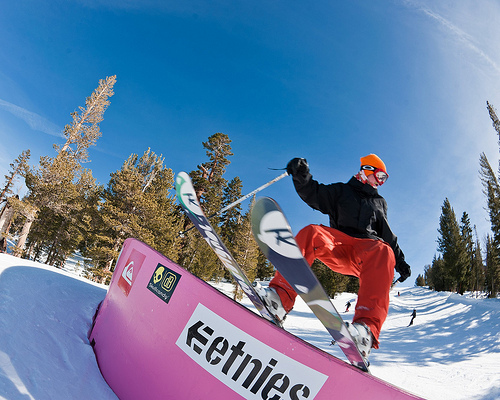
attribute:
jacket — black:
[280, 169, 417, 263]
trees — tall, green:
[31, 48, 234, 293]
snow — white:
[374, 283, 484, 398]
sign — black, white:
[169, 170, 366, 305]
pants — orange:
[255, 216, 422, 353]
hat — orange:
[355, 150, 389, 177]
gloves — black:
[233, 132, 330, 208]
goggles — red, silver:
[358, 164, 389, 186]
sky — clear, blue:
[2, 8, 497, 210]